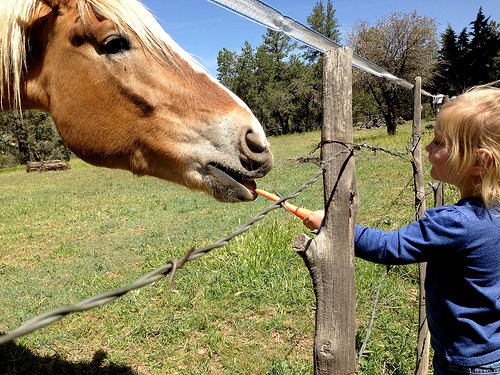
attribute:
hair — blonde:
[449, 104, 499, 155]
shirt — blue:
[348, 198, 498, 362]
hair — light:
[446, 101, 493, 148]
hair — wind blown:
[435, 85, 499, 205]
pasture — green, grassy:
[0, 113, 462, 373]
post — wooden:
[320, 55, 357, 367]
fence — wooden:
[89, 22, 466, 373]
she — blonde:
[392, 97, 499, 302]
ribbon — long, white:
[429, 91, 444, 106]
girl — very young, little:
[304, 82, 484, 372]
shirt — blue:
[345, 200, 483, 371]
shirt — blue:
[351, 85, 480, 373]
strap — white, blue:
[211, 0, 414, 91]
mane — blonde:
[4, 3, 211, 123]